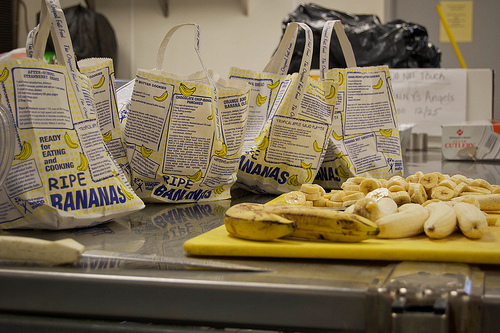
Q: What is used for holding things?
A: A bag.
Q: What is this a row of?
A: Bags with handles.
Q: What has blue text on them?
A: Paper bags.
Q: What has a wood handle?
A: A knife.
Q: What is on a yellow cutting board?
A: Bananas.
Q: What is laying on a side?
A: Cutting knife.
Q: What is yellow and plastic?
A: Cutting board.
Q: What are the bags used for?
A: Carrying bananas.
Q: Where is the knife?
A: On table.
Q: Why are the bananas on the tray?
A: To be chopped.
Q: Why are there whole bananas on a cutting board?
A: They are waiting to get cut up.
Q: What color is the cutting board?
A: Yellow.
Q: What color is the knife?
A: White and silver.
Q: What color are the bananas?
A: Off white.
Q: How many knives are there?
A: One.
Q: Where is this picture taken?
A: In a kitchen.